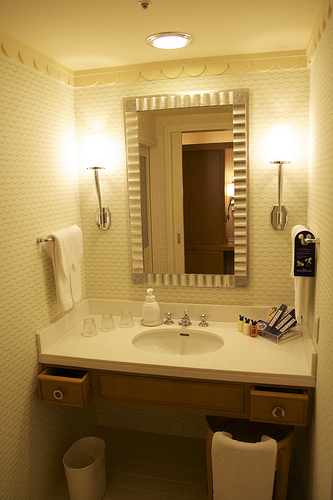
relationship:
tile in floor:
[161, 464, 171, 480] [113, 425, 209, 495]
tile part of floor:
[161, 464, 171, 480] [48, 423, 228, 499]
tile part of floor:
[161, 464, 171, 480] [52, 423, 297, 498]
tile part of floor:
[161, 464, 171, 480] [52, 421, 213, 499]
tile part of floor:
[161, 464, 171, 480] [97, 425, 206, 497]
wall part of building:
[0, 32, 99, 496] [0, 2, 331, 499]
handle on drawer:
[271, 405, 287, 419] [247, 389, 310, 430]